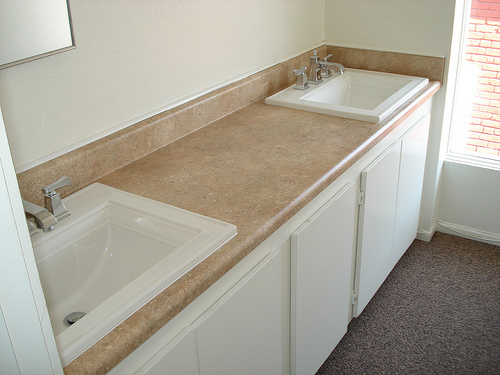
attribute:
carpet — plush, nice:
[312, 232, 499, 372]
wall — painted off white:
[1, 0, 456, 244]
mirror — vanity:
[2, 0, 82, 79]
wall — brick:
[462, 17, 497, 167]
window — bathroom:
[434, 6, 498, 169]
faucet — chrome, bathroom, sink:
[311, 55, 348, 82]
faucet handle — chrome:
[283, 37, 371, 104]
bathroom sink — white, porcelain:
[21, 181, 239, 368]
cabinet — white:
[354, 110, 442, 319]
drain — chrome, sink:
[61, 309, 83, 324]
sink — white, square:
[25, 180, 236, 371]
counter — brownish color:
[190, 117, 333, 201]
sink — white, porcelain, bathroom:
[263, 67, 428, 123]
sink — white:
[271, 60, 428, 115]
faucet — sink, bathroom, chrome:
[20, 199, 59, 235]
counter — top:
[142, 100, 345, 213]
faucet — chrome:
[18, 171, 100, 238]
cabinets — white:
[174, 118, 428, 373]